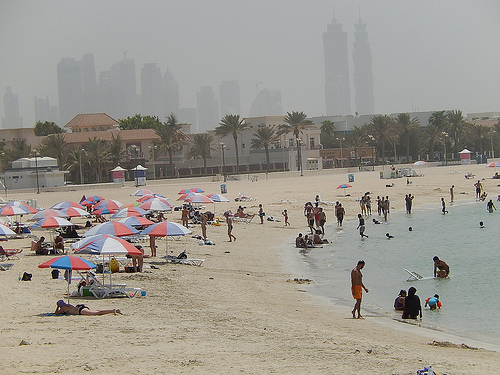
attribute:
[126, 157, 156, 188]
pergola — blue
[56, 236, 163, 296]
umbrella — red, blue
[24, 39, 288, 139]
buildings — tall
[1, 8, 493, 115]
fog — white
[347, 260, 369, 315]
man — orange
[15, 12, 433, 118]
buildings — behind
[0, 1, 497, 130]
sky — foggy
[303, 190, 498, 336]
water — shallow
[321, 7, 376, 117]
skyscrapers — tall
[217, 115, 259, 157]
palm tree — single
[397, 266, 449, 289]
chair — lounge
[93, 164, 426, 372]
beach — red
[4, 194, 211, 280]
umbrellas — clustered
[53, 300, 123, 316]
woman — laying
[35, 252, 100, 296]
umbrella — colorful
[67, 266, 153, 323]
chairs — white, under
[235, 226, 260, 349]
sand — brown